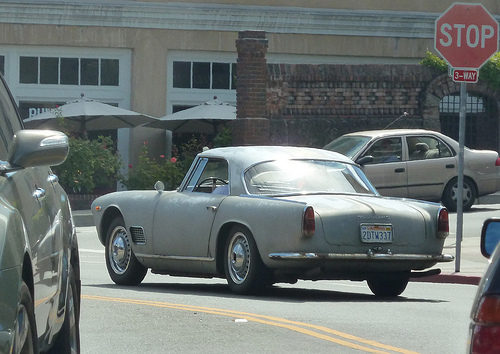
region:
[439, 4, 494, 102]
stop sign on the side of the road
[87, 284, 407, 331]
two yellow lines in the middle of the road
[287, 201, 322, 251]
oval tail lights on a car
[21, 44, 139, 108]
five windows on a building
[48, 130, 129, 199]
shrubs in front of the building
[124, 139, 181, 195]
flowers on the green plants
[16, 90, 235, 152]
two white canopies in front of the building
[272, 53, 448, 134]
brick wall in front of building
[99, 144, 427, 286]
car on the corner of the road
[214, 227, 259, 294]
tire with white walls and shinny hub caps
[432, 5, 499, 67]
An octagonal stop sign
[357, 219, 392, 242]
The license plate on a car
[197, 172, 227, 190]
A steering wheel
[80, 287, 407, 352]
Yellow lines on the road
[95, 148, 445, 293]
An old-fashioned car stopped in the street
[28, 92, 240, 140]
Two umbrellas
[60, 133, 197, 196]
Plants with flowers by the road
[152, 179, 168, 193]
A car's side mirror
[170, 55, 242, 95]
Windows on a building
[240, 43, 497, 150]
A brick entryway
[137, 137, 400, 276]
grey car at stop sign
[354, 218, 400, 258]
black and white license plate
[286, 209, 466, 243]
car has red taillights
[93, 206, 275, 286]
car has black wheels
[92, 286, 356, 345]
double yellow line on road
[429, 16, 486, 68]
red and white stop sign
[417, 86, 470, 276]
stop sign on grey post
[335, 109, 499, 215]
gold car behind stop sign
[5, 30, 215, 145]
grey wall on building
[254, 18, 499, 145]
brick fence behind gold car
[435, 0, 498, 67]
stop sign on corner of street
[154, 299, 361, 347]
double yellow line in the road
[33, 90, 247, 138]
two white umbrellas in front of store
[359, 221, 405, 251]
license plate on the back of car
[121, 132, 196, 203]
flowers in front of umbrella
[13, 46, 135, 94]
five windows in a row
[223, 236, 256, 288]
hubcap on the car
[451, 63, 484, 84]
3-way on bottom of stop sign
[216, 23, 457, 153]
brick wall next to car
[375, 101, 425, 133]
attenna on the car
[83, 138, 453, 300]
older car at a stop sign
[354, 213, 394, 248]
licence plate on a classic car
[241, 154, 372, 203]
glare on the back window of a car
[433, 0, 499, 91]
three way stop sign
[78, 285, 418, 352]
two yellow stripes on the road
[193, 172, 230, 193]
black steering wheel in a classic car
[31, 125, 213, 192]
bushes outside of a building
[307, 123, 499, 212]
light colored car with a stripe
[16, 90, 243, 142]
two white colored umbrellas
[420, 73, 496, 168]
archway in a brick wall